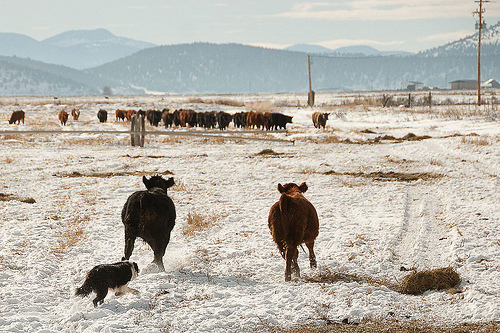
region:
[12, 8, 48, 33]
white clouds in blue sky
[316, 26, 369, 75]
white clouds in blue sky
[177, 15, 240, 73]
white clouds in blue sky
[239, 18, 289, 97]
white clouds in blue sky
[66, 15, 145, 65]
white clouds in blue sky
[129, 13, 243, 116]
white clouds in blue sky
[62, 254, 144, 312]
black dog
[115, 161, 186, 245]
brown cow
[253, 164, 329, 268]
brown cow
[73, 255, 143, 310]
A black and white cattle dog.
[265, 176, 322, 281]
A brown cow running.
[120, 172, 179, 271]
A black cow in the snow.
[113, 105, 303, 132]
A herd of cows.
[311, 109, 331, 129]
A cow standing alone.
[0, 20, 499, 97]
A distant mountain range.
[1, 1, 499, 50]
A distant cloudy sky.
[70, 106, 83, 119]
A brown and white cow.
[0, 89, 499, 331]
A snow covered pasture.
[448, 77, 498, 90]
Two distant buildings.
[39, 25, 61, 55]
white clouds in blue sky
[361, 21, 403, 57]
white clouds in blue sky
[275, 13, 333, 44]
white clouds in blue sky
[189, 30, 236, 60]
white clouds in blue sky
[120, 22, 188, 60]
white clouds in blue sky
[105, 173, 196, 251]
cow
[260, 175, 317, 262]
cow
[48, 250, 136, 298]
dog running behind cows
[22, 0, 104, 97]
white clouds in blue sky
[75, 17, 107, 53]
white clouds in blue sky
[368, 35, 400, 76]
white clouds in blue sky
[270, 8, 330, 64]
white clouds in blue sky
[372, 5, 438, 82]
white clouds in blue sky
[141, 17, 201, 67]
white clouds in blue sky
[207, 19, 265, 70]
white clouds in blue sky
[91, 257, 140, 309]
black and white dog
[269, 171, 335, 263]
brown cow running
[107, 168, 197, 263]
brown cow running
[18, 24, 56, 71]
white clouds in blue sky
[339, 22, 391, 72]
white clouds in blue sky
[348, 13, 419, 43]
white clouds in blue sky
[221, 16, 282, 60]
white clouds in blue sky